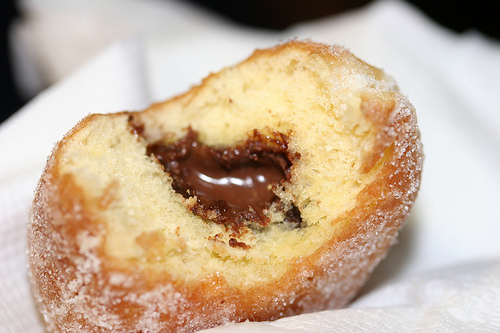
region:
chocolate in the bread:
[160, 95, 320, 225]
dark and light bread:
[305, 105, 445, 230]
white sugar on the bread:
[350, 135, 440, 240]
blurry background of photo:
[400, 15, 465, 55]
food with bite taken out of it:
[20, 35, 460, 290]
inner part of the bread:
[130, 111, 320, 221]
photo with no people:
[15, 7, 490, 302]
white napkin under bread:
[395, 20, 496, 141]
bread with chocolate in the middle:
[92, 78, 402, 268]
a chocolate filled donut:
[25, 40, 424, 330]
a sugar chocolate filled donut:
[25, 35, 424, 332]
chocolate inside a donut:
[157, 139, 292, 223]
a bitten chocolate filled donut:
[24, 35, 426, 331]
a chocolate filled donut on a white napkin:
[0, 0, 497, 330]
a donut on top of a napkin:
[0, 0, 496, 328]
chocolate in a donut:
[148, 136, 283, 207]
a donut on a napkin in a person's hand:
[1, 1, 496, 331]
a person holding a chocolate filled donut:
[2, 3, 498, 330]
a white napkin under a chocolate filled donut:
[1, 1, 498, 331]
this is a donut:
[10, 29, 435, 331]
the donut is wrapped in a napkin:
[1, 19, 481, 331]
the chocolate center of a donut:
[138, 131, 312, 223]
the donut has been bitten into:
[17, 35, 434, 332]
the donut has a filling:
[23, 20, 498, 330]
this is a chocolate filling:
[135, 127, 301, 227]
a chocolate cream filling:
[150, 135, 336, 215]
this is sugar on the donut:
[37, 255, 97, 305]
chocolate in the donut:
[145, 106, 335, 236]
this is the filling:
[125, 113, 316, 224]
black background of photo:
[228, 0, 305, 20]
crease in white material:
[117, 43, 163, 98]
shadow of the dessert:
[390, 248, 411, 279]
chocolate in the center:
[198, 164, 258, 197]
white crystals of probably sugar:
[40, 228, 90, 291]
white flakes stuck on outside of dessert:
[54, 254, 118, 329]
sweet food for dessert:
[26, 35, 423, 331]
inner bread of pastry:
[121, 180, 181, 222]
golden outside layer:
[361, 188, 376, 213]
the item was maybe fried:
[21, 35, 424, 331]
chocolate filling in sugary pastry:
[27, 11, 409, 318]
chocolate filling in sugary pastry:
[40, 56, 467, 331]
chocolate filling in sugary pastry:
[33, 33, 467, 331]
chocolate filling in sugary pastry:
[10, 37, 456, 329]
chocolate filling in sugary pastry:
[31, 43, 453, 329]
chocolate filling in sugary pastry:
[31, 45, 422, 329]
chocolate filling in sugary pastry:
[31, 50, 461, 331]